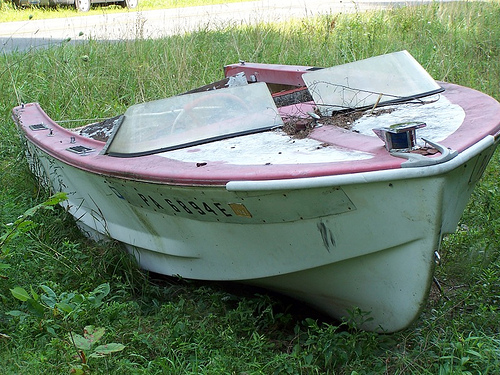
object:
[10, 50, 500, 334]
boat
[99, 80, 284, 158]
windshield